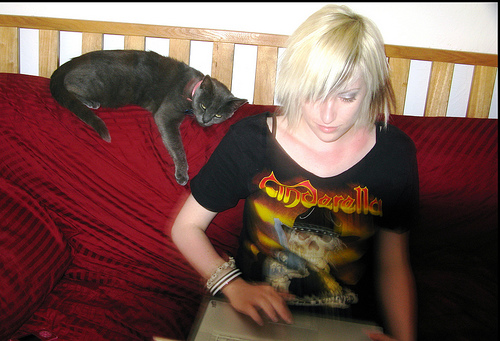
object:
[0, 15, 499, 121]
frame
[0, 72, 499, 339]
couch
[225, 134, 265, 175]
black/cinderella skirt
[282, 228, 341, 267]
skeleton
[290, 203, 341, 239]
cowboy hat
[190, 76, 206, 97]
pink collar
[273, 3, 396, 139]
hair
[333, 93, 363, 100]
eye shadow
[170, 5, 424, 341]
girl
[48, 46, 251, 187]
cat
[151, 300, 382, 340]
laptop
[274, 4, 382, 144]
head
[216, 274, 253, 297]
wrist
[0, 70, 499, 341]
cushion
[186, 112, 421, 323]
shirt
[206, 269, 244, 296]
bracelet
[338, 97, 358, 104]
mascara